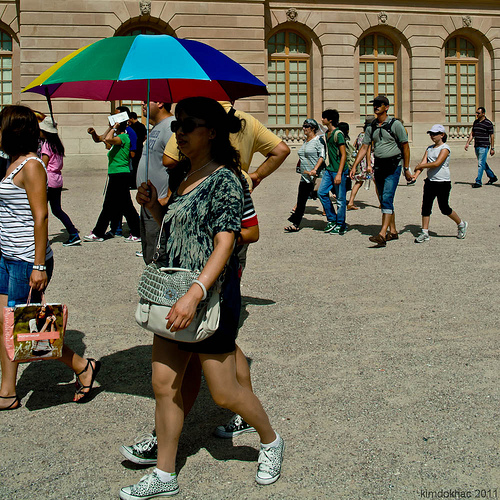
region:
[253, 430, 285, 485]
canvas shoe on foot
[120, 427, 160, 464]
A converse shoe on a foot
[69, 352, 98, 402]
A casual dress shoe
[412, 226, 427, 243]
Athletic shoe on a foot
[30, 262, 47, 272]
A watch on a wrist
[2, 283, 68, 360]
A pink bag in hand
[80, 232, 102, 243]
A Nike branded shoe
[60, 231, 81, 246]
Blue and black shoe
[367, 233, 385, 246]
A brown shoe on a foot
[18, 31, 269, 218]
A rainbow umbrella being held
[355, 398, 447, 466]
the ground is asphalt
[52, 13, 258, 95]
the umrella is rainbow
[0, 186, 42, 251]
the tank top is striped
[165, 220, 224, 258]
pattern on the shirt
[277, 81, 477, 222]
people in a group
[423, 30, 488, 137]
window on the building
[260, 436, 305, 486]
the shoe is sneaker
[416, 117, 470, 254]
this is a person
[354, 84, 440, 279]
this is a person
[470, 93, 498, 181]
this is a person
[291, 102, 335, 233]
this is a person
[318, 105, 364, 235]
this is a person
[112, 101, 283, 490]
this is a person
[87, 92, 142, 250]
this is a person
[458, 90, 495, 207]
this is a person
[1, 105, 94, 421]
this is a person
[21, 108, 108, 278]
this is a person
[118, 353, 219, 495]
leg of a person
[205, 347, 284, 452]
leg of a person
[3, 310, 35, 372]
leg of a person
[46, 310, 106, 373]
leg of a person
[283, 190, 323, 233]
leg of a person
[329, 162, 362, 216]
leg of a person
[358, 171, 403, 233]
leg of a person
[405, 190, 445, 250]
leg of a person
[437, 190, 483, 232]
leg of a person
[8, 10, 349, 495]
Person holding an umbrella over her head to protect herself from the sun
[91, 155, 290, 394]
Woman carrying a shoulder bag over her shoulder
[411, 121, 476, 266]
Woman wearing a hat on her head and holding hands with her man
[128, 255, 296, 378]
Woman is wearing a white bracelet on her arm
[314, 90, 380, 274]
Young boy carrying a backpack as he walks down the path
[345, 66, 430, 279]
Man wearing a hat and a backpack as he walks down the path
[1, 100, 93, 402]
Woman in a striped tank top walking down the street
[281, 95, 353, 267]
Woman with sunglasses walking down the road with her son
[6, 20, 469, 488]
Several people in the bright sun walking on the gravel near the church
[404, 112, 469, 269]
girl wearing a hat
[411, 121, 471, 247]
girl wearing black shirts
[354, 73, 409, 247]
man wearing a green shirt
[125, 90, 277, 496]
woman holding umbrella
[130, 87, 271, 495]
woman wearing black shorts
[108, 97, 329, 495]
woman holding a purse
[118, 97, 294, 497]
woman wearing tennis shoes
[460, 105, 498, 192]
man wearing blue jeans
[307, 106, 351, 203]
a person walking on the sidewalk